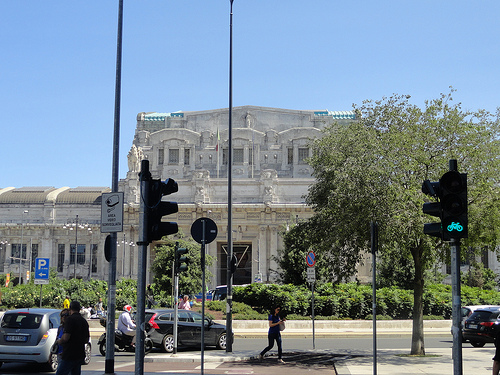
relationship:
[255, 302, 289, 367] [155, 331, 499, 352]
lady walking down street